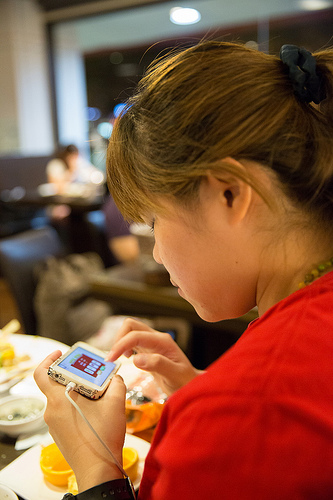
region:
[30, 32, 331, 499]
Woman holding a cellphone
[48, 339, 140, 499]
White smartphone with white cord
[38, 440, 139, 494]
Slices of oranges on a plate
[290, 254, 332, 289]
Round beads on a necklace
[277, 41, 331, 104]
Black scrunchie in a womans hair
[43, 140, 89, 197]
Woman sitting at a restaurant table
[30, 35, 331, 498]
Woman using a cellphone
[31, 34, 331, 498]
Woman wearing a red shirt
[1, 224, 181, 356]
Bag resting on a booth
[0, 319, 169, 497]
Table off food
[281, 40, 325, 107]
black hair tie on head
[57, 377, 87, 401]
cord plugged into phone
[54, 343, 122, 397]
white cell phone in hand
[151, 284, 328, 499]
red shirt on woman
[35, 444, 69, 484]
yellow pieces on plate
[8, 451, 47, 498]
white plate on table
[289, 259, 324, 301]
beaded necklace on woman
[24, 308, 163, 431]
fingers touching phone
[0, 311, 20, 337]
brown chop stick on plate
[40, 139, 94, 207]
woman sitting at table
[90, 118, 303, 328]
face of the girl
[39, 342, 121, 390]
a mobile phone in top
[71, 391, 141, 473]
a wire of head hone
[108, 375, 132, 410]
finger of the hand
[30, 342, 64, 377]
fingers of the girl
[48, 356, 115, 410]
ports of the mobile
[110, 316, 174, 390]
thumb fingers of the girl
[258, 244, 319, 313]
neck of the girl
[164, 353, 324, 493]
a girl wearing red shirt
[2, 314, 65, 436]
a plate in the table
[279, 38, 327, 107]
hair bow in her hair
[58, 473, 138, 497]
black watch on her wrist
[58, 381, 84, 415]
white wire in phone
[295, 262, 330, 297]
necklace around woman's neck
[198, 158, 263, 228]
the woman's left ear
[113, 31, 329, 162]
the woman's brown hair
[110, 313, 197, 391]
the woman's right hand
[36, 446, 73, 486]
yellow container on plate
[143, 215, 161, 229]
woman's left eye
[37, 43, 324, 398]
young woman looking down at electronic device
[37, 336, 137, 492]
white device in hand with wire over wrist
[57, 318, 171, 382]
curled finger tapping on screen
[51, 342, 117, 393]
screen with white ovals in red square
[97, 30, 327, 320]
brown hair pulled back with black tie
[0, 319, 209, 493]
white plates with food under hands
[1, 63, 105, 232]
person sitting in corner by window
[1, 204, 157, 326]
brown bag between chair and table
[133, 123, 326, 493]
woman wearing red blouse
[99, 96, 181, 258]
straight bangs over forehead